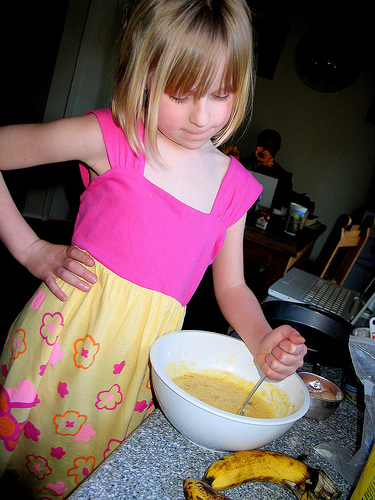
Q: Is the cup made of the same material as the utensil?
A: No, the cup is made of plastic and the utensil is made of metal.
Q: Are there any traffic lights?
A: No, there are no traffic lights.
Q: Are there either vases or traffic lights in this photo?
A: No, there are no traffic lights or vases.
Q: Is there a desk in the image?
A: Yes, there is a desk.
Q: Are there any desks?
A: Yes, there is a desk.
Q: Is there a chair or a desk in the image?
A: Yes, there is a desk.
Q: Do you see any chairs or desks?
A: Yes, there is a desk.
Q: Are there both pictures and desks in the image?
A: No, there is a desk but no pictures.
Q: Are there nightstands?
A: No, there are no nightstands.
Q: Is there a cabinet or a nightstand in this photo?
A: No, there are no nightstands or cabinets.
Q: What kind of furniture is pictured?
A: The furniture is a desk.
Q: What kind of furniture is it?
A: The piece of furniture is a desk.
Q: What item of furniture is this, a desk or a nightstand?
A: That is a desk.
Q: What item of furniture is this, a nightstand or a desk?
A: That is a desk.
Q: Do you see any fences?
A: No, there are no fences.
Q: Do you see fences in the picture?
A: No, there are no fences.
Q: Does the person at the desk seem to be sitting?
A: Yes, the person is sitting.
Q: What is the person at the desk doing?
A: The person is sitting.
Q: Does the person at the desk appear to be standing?
A: No, the person is sitting.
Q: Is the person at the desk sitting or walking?
A: The person is sitting.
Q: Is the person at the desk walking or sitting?
A: The person is sitting.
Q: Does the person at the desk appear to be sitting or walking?
A: The person is sitting.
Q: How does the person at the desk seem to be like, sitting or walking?
A: The person is sitting.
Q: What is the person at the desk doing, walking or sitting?
A: The person is sitting.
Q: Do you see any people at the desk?
A: Yes, there is a person at the desk.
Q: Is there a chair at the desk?
A: No, there is a person at the desk.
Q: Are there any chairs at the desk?
A: No, there is a person at the desk.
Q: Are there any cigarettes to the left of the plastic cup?
A: Yes, there are cigarettes to the left of the cup.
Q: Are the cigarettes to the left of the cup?
A: Yes, the cigarettes are to the left of the cup.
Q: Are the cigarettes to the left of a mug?
A: No, the cigarettes are to the left of the cup.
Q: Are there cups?
A: Yes, there is a cup.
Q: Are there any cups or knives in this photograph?
A: Yes, there is a cup.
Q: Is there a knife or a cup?
A: Yes, there is a cup.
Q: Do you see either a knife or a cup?
A: Yes, there is a cup.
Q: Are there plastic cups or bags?
A: Yes, there is a plastic cup.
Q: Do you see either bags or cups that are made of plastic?
A: Yes, the cup is made of plastic.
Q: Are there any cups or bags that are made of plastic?
A: Yes, the cup is made of plastic.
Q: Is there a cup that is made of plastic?
A: Yes, there is a cup that is made of plastic.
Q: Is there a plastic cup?
A: Yes, there is a cup that is made of plastic.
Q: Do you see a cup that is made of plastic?
A: Yes, there is a cup that is made of plastic.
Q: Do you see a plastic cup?
A: Yes, there is a cup that is made of plastic.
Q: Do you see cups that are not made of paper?
A: Yes, there is a cup that is made of plastic.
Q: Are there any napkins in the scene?
A: No, there are no napkins.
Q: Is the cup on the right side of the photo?
A: Yes, the cup is on the right of the image.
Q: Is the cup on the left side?
A: No, the cup is on the right of the image.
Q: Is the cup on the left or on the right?
A: The cup is on the right of the image.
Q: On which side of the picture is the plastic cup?
A: The cup is on the right of the image.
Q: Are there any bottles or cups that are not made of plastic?
A: No, there is a cup but it is made of plastic.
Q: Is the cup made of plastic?
A: Yes, the cup is made of plastic.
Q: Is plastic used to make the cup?
A: Yes, the cup is made of plastic.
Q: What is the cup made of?
A: The cup is made of plastic.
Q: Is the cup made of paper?
A: No, the cup is made of plastic.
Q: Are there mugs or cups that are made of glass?
A: No, there is a cup but it is made of plastic.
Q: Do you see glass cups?
A: No, there is a cup but it is made of plastic.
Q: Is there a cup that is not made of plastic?
A: No, there is a cup but it is made of plastic.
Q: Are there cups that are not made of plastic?
A: No, there is a cup but it is made of plastic.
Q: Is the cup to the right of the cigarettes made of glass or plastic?
A: The cup is made of plastic.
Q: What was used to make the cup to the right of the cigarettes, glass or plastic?
A: The cup is made of plastic.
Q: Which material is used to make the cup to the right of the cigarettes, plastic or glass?
A: The cup is made of plastic.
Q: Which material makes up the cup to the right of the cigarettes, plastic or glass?
A: The cup is made of plastic.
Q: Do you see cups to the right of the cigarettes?
A: Yes, there is a cup to the right of the cigarettes.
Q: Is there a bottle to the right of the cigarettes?
A: No, there is a cup to the right of the cigarettes.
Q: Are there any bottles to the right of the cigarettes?
A: No, there is a cup to the right of the cigarettes.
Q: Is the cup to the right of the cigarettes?
A: Yes, the cup is to the right of the cigarettes.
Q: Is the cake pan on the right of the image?
A: Yes, the cake pan is on the right of the image.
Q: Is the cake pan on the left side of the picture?
A: No, the cake pan is on the right of the image.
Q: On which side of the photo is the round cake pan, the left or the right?
A: The cake pan is on the right of the image.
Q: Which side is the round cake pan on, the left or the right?
A: The cake pan is on the right of the image.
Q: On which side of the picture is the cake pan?
A: The cake pan is on the right of the image.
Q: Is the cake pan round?
A: Yes, the cake pan is round.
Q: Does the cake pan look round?
A: Yes, the cake pan is round.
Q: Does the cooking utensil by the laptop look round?
A: Yes, the cake pan is round.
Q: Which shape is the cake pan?
A: The cake pan is round.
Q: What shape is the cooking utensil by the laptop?
A: The cake pan is round.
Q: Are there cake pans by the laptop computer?
A: Yes, there is a cake pan by the laptop computer.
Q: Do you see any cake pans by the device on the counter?
A: Yes, there is a cake pan by the laptop computer.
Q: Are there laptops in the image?
A: Yes, there is a laptop.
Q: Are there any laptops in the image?
A: Yes, there is a laptop.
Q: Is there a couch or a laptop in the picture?
A: Yes, there is a laptop.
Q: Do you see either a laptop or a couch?
A: Yes, there is a laptop.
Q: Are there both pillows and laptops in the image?
A: No, there is a laptop but no pillows.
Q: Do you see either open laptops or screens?
A: Yes, there is an open laptop.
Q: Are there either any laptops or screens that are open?
A: Yes, the laptop is open.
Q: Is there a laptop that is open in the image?
A: Yes, there is an open laptop.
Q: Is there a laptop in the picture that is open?
A: Yes, there is a laptop that is open.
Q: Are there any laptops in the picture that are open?
A: Yes, there is a laptop that is open.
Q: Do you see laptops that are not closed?
A: Yes, there is a open laptop.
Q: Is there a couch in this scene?
A: No, there are no couches.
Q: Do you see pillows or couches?
A: No, there are no couches or pillows.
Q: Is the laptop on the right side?
A: Yes, the laptop is on the right of the image.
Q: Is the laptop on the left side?
A: No, the laptop is on the right of the image.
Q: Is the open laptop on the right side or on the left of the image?
A: The laptop is on the right of the image.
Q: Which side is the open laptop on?
A: The laptop is on the right of the image.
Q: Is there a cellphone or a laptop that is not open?
A: No, there is a laptop but it is open.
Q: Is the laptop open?
A: Yes, the laptop is open.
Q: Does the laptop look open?
A: Yes, the laptop is open.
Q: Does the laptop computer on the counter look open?
A: Yes, the laptop computer is open.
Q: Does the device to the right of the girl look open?
A: Yes, the laptop computer is open.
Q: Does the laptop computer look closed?
A: No, the laptop computer is open.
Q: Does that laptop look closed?
A: No, the laptop is open.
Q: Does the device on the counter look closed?
A: No, the laptop is open.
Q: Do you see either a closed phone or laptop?
A: No, there is a laptop but it is open.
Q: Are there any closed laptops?
A: No, there is a laptop but it is open.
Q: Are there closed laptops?
A: No, there is a laptop but it is open.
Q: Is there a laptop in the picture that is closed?
A: No, there is a laptop but it is open.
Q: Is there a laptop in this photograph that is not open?
A: No, there is a laptop but it is open.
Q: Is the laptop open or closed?
A: The laptop is open.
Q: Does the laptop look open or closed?
A: The laptop is open.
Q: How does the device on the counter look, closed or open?
A: The laptop is open.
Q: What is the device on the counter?
A: The device is a laptop.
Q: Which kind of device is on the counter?
A: The device is a laptop.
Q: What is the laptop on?
A: The laptop is on the counter.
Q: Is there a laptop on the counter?
A: Yes, there is a laptop on the counter.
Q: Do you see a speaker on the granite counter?
A: No, there is a laptop on the counter.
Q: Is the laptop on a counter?
A: Yes, the laptop is on a counter.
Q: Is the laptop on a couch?
A: No, the laptop is on a counter.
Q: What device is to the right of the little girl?
A: The device is a laptop.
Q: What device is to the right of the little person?
A: The device is a laptop.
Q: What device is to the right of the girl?
A: The device is a laptop.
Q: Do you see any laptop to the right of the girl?
A: Yes, there is a laptop to the right of the girl.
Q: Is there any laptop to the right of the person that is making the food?
A: Yes, there is a laptop to the right of the girl.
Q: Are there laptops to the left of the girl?
A: No, the laptop is to the right of the girl.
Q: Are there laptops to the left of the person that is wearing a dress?
A: No, the laptop is to the right of the girl.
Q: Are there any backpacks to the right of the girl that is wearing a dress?
A: No, there is a laptop to the right of the girl.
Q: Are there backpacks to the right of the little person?
A: No, there is a laptop to the right of the girl.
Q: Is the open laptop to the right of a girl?
A: Yes, the laptop is to the right of a girl.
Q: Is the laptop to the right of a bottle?
A: No, the laptop is to the right of a girl.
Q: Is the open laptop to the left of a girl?
A: No, the laptop computer is to the right of a girl.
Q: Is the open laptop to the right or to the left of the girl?
A: The laptop computer is to the right of the girl.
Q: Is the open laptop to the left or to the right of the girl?
A: The laptop computer is to the right of the girl.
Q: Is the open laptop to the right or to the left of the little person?
A: The laptop computer is to the right of the girl.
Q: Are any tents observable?
A: No, there are no tents.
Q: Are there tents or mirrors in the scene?
A: No, there are no tents or mirrors.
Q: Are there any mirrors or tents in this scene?
A: No, there are no tents or mirrors.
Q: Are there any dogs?
A: No, there are no dogs.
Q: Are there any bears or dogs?
A: No, there are no dogs or bears.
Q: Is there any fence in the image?
A: No, there are no fences.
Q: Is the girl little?
A: Yes, the girl is little.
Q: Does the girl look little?
A: Yes, the girl is little.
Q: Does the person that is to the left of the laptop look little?
A: Yes, the girl is little.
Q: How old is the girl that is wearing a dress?
A: The girl is little.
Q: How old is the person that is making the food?
A: The girl is little.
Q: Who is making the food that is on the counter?
A: The girl is making the food.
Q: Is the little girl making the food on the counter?
A: Yes, the girl is making the food.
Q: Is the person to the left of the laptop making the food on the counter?
A: Yes, the girl is making the food.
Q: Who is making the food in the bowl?
A: The girl is making the food.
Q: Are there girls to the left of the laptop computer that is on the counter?
A: Yes, there is a girl to the left of the laptop.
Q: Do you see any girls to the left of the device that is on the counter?
A: Yes, there is a girl to the left of the laptop.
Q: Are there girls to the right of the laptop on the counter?
A: No, the girl is to the left of the laptop computer.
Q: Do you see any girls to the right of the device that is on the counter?
A: No, the girl is to the left of the laptop computer.